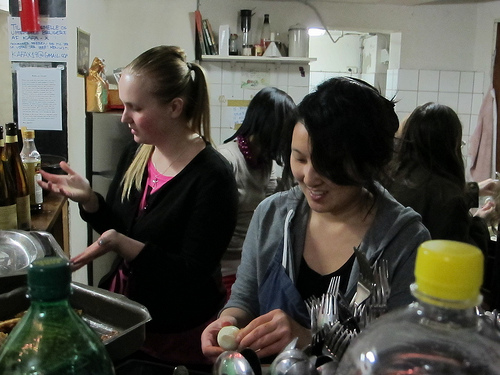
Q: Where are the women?
A: Kitchen.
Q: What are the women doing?
A: Cooking.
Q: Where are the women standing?
A: Kitchen.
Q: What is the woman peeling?
A: Eggs.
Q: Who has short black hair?
A: The woman.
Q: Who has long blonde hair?
A: The woman.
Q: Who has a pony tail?
A: The woman.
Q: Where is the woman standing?
A: Woman standing in a kitchen.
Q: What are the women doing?
A: These ladies are working in a kitchen.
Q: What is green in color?
A: This bottle & cap are green.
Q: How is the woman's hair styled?
A: This lady has her hair in a pony tail.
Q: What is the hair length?
A: This lady appears to have short hair.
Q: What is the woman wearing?
A: She is wearing a grey hoodie.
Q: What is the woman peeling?
A: This lady is peeling an egg.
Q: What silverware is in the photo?
A: Forks & spoons are in the photo.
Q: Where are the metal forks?
A: In front of the woman.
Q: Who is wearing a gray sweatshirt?
A: The woman on the right.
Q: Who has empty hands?
A: The woman on the left.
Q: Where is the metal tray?
A: In front of the women.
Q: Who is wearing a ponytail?
A: The woman on the left.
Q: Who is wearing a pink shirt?
A: The woman on the left.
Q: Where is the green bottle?
A: In front of the metal pan.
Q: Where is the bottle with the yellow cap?
A: In front of the forks.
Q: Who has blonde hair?
A: The woman on the left.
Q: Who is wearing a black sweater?
A: The woman on the left.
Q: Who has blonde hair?
A: The woman on the left.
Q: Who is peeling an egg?
A: The woman on the right.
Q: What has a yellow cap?
A: The bottle on the right.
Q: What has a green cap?
A: The green bottle.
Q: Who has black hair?
A: The woman on the right.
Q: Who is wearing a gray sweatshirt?
A: The woman on the right.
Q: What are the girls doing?
A: Working.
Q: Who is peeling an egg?
A: The girl with brown hair.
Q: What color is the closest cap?
A: Yellow.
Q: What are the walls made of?
A: Tile and drywall.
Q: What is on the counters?
A: Kitchen goods.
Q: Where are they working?
A: In a kitchen.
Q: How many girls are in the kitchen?
A: Four.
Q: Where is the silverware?
A: In front of the girl.